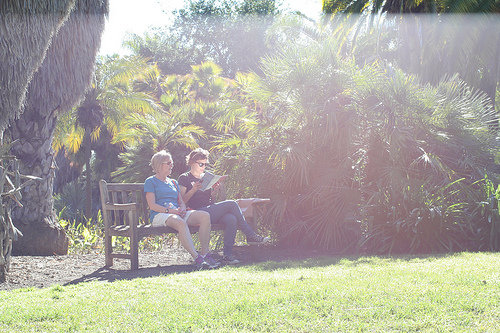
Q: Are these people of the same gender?
A: Yes, all the people are female.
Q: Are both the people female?
A: Yes, all the people are female.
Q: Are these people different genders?
A: No, all the people are female.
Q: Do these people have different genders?
A: No, all the people are female.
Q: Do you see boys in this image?
A: No, there are no boys.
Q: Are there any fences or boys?
A: No, there are no boys or fences.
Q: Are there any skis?
A: No, there are no skis.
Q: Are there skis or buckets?
A: No, there are no skis or buckets.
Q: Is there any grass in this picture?
A: Yes, there is grass.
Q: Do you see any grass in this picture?
A: Yes, there is grass.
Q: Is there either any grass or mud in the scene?
A: Yes, there is grass.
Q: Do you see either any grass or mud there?
A: Yes, there is grass.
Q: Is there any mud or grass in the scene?
A: Yes, there is grass.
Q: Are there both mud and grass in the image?
A: No, there is grass but no mud.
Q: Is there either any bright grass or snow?
A: Yes, there is bright grass.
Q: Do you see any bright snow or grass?
A: Yes, there is bright grass.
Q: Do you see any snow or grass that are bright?
A: Yes, the grass is bright.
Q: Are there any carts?
A: No, there are no carts.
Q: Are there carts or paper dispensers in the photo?
A: No, there are no carts or paper dispensers.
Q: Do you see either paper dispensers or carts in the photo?
A: No, there are no carts or paper dispensers.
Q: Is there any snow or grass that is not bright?
A: No, there is grass but it is bright.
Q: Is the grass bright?
A: Yes, the grass is bright.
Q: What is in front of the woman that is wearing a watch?
A: The grass is in front of the woman.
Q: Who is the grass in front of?
A: The grass is in front of the woman.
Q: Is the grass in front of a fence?
A: No, the grass is in front of a woman.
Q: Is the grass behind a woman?
A: No, the grass is in front of a woman.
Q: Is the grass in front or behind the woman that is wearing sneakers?
A: The grass is in front of the woman.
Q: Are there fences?
A: No, there are no fences.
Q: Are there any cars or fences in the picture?
A: No, there are no fences or cars.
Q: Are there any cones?
A: No, there are no cones.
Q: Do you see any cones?
A: No, there are no cones.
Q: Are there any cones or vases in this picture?
A: No, there are no cones or vases.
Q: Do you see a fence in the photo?
A: No, there are no fences.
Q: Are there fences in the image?
A: No, there are no fences.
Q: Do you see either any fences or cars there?
A: No, there are no fences or cars.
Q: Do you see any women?
A: Yes, there is a woman.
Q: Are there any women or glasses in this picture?
A: Yes, there is a woman.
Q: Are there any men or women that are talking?
A: Yes, the woman is talking.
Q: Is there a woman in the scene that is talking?
A: Yes, there is a woman that is talking.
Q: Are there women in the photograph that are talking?
A: Yes, there is a woman that is talking.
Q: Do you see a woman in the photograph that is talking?
A: Yes, there is a woman that is talking.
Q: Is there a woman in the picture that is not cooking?
A: Yes, there is a woman that is talking.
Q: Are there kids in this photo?
A: No, there are no kids.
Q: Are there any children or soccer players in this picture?
A: No, there are no children or soccer players.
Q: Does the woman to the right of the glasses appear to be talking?
A: Yes, the woman is talking.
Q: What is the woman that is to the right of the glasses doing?
A: The woman is talking.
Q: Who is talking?
A: The woman is talking.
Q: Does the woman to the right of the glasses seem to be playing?
A: No, the woman is talking.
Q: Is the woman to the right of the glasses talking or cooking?
A: The woman is talking.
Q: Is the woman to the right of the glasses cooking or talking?
A: The woman is talking.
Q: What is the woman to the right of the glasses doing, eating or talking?
A: The woman is talking.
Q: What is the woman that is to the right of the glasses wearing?
A: The woman is wearing a shirt.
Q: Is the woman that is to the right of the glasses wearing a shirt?
A: Yes, the woman is wearing a shirt.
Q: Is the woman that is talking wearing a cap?
A: No, the woman is wearing a shirt.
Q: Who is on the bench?
A: The woman is on the bench.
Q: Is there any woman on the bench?
A: Yes, there is a woman on the bench.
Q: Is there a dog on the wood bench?
A: No, there is a woman on the bench.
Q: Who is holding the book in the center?
A: The woman is holding the book.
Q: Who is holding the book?
A: The woman is holding the book.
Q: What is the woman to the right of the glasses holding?
A: The woman is holding the book.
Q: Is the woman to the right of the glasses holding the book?
A: Yes, the woman is holding the book.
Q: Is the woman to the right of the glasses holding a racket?
A: No, the woman is holding the book.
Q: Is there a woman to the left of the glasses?
A: No, the woman is to the right of the glasses.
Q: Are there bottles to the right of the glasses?
A: No, there is a woman to the right of the glasses.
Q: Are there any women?
A: Yes, there is a woman.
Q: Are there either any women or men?
A: Yes, there is a woman.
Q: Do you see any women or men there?
A: Yes, there is a woman.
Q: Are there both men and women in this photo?
A: No, there is a woman but no men.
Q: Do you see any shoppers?
A: No, there are no shoppers.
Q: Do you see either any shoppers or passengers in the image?
A: No, there are no shoppers or passengers.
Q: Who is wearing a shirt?
A: The woman is wearing a shirt.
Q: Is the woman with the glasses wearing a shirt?
A: Yes, the woman is wearing a shirt.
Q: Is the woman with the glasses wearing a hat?
A: No, the woman is wearing a shirt.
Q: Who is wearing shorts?
A: The woman is wearing shorts.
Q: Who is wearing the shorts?
A: The woman is wearing shorts.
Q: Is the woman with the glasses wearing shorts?
A: Yes, the woman is wearing shorts.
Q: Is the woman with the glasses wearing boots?
A: No, the woman is wearing shorts.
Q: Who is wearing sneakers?
A: The woman is wearing sneakers.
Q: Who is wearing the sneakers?
A: The woman is wearing sneakers.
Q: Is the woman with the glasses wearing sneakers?
A: Yes, the woman is wearing sneakers.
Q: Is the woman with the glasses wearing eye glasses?
A: No, the woman is wearing sneakers.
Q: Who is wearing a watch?
A: The woman is wearing a watch.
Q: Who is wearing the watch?
A: The woman is wearing a watch.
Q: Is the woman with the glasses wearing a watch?
A: Yes, the woman is wearing a watch.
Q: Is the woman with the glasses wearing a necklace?
A: No, the woman is wearing a watch.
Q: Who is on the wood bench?
A: The woman is on the bench.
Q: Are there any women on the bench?
A: Yes, there is a woman on the bench.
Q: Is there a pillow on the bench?
A: No, there is a woman on the bench.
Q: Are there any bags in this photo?
A: No, there are no bags.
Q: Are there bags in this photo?
A: No, there are no bags.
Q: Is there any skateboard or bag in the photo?
A: No, there are no bags or skateboards.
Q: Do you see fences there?
A: No, there are no fences.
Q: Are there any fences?
A: No, there are no fences.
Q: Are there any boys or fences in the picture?
A: No, there are no fences or boys.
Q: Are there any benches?
A: Yes, there is a bench.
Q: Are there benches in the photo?
A: Yes, there is a bench.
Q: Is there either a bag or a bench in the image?
A: Yes, there is a bench.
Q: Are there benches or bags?
A: Yes, there is a bench.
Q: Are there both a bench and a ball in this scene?
A: No, there is a bench but no balls.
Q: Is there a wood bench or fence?
A: Yes, there is a wood bench.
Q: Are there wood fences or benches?
A: Yes, there is a wood bench.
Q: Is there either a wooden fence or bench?
A: Yes, there is a wood bench.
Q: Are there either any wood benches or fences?
A: Yes, there is a wood bench.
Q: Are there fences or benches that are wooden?
A: Yes, the bench is wooden.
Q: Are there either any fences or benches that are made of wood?
A: Yes, the bench is made of wood.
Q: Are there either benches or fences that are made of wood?
A: Yes, the bench is made of wood.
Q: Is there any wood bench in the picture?
A: Yes, there is a wood bench.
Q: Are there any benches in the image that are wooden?
A: Yes, there is a bench that is wooden.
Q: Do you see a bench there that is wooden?
A: Yes, there is a bench that is wooden.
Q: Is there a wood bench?
A: Yes, there is a bench that is made of wood.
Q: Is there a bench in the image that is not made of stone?
A: Yes, there is a bench that is made of wood.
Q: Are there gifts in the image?
A: No, there are no gifts.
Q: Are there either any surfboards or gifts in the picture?
A: No, there are no gifts or surfboards.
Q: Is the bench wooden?
A: Yes, the bench is wooden.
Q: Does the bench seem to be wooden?
A: Yes, the bench is wooden.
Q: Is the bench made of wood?
A: Yes, the bench is made of wood.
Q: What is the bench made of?
A: The bench is made of wood.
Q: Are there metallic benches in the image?
A: No, there is a bench but it is wooden.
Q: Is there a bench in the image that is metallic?
A: No, there is a bench but it is wooden.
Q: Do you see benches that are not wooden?
A: No, there is a bench but it is wooden.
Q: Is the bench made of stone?
A: No, the bench is made of wood.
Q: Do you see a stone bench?
A: No, there is a bench but it is made of wood.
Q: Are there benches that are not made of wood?
A: No, there is a bench but it is made of wood.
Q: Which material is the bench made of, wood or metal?
A: The bench is made of wood.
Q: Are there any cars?
A: No, there are no cars.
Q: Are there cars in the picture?
A: No, there are no cars.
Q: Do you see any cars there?
A: No, there are no cars.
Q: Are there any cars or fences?
A: No, there are no cars or fences.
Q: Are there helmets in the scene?
A: No, there are no helmets.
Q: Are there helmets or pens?
A: No, there are no helmets or pens.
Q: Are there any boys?
A: No, there are no boys.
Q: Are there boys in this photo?
A: No, there are no boys.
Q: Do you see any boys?
A: No, there are no boys.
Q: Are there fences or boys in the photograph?
A: No, there are no boys or fences.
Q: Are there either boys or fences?
A: No, there are no boys or fences.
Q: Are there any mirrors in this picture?
A: No, there are no mirrors.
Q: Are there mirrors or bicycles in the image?
A: No, there are no mirrors or bicycles.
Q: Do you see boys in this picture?
A: No, there are no boys.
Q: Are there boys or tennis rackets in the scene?
A: No, there are no boys or tennis rackets.